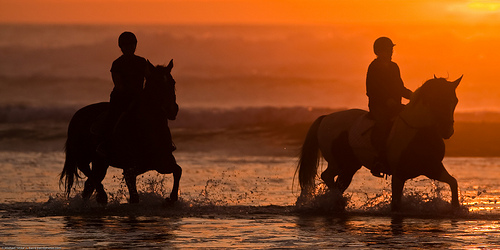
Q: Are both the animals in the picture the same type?
A: Yes, all the animals are horses.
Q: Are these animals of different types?
A: No, all the animals are horses.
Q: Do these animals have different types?
A: No, all the animals are horses.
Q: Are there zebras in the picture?
A: No, there are no zebras.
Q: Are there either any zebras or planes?
A: No, there are no zebras or planes.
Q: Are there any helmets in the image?
A: Yes, there is a helmet.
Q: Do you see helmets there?
A: Yes, there is a helmet.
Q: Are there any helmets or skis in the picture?
A: Yes, there is a helmet.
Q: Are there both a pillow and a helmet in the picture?
A: No, there is a helmet but no pillows.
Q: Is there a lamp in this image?
A: No, there are no lamps.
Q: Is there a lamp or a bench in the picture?
A: No, there are no lamps or benches.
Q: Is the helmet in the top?
A: Yes, the helmet is in the top of the image.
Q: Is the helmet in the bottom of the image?
A: No, the helmet is in the top of the image.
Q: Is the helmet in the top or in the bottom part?
A: The helmet is in the top of the image.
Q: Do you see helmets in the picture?
A: Yes, there is a helmet.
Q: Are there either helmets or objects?
A: Yes, there is a helmet.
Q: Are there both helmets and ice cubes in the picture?
A: No, there is a helmet but no ice cubes.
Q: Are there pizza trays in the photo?
A: No, there are no pizza trays.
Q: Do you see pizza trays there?
A: No, there are no pizza trays.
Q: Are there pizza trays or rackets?
A: No, there are no pizza trays or rackets.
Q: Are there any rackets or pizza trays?
A: No, there are no pizza trays or rackets.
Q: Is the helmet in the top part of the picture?
A: Yes, the helmet is in the top of the image.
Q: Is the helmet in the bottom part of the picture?
A: No, the helmet is in the top of the image.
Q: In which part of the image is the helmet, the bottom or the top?
A: The helmet is in the top of the image.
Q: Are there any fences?
A: No, there are no fences.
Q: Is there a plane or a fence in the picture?
A: No, there are no fences or airplanes.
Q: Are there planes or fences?
A: No, there are no fences or planes.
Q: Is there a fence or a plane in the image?
A: No, there are no fences or airplanes.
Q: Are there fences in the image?
A: No, there are no fences.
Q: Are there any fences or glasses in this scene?
A: No, there are no fences or glasses.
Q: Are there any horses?
A: Yes, there is a horse.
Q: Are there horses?
A: Yes, there is a horse.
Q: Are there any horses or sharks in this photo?
A: Yes, there is a horse.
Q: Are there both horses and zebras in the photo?
A: No, there is a horse but no zebras.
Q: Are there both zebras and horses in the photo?
A: No, there is a horse but no zebras.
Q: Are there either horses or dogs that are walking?
A: Yes, the horse is walking.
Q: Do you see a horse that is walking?
A: Yes, there is a horse that is walking.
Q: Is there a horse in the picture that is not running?
A: Yes, there is a horse that is walking.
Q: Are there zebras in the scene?
A: No, there are no zebras.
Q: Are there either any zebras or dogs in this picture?
A: No, there are no zebras or dogs.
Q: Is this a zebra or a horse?
A: This is a horse.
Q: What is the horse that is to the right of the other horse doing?
A: The horse is walking.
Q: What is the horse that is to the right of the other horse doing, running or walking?
A: The horse is walking.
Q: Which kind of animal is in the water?
A: The animal is a horse.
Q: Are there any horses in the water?
A: Yes, there is a horse in the water.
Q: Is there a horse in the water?
A: Yes, there is a horse in the water.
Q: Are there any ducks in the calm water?
A: No, there is a horse in the water.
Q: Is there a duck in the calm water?
A: No, there is a horse in the water.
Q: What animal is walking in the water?
A: The horse is walking in the water.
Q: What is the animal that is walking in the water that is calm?
A: The animal is a horse.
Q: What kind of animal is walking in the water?
A: The animal is a horse.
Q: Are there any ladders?
A: No, there are no ladders.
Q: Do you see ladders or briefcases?
A: No, there are no ladders or briefcases.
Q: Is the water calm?
A: Yes, the water is calm.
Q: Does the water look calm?
A: Yes, the water is calm.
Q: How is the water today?
A: The water is calm.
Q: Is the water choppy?
A: No, the water is calm.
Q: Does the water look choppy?
A: No, the water is calm.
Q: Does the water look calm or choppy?
A: The water is calm.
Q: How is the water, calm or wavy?
A: The water is calm.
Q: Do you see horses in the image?
A: Yes, there is a horse.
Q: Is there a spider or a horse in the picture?
A: Yes, there is a horse.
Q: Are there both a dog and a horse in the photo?
A: No, there is a horse but no dogs.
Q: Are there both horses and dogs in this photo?
A: No, there is a horse but no dogs.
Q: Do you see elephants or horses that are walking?
A: Yes, the horse is walking.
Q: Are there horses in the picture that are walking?
A: Yes, there is a horse that is walking.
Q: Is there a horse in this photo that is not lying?
A: Yes, there is a horse that is walking.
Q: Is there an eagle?
A: No, there are no eagles.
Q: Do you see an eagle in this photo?
A: No, there are no eagles.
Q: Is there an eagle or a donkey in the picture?
A: No, there are no eagles or donkeys.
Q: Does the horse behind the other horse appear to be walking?
A: Yes, the horse is walking.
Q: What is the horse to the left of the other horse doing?
A: The horse is walking.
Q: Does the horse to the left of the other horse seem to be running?
A: No, the horse is walking.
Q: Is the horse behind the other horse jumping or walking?
A: The horse is walking.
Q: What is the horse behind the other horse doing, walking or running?
A: The horse is walking.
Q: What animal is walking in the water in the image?
A: The horse is walking in the water.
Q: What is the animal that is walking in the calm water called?
A: The animal is a horse.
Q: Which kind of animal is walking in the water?
A: The animal is a horse.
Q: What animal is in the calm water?
A: The horse is in the water.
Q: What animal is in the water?
A: The horse is in the water.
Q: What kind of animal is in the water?
A: The animal is a horse.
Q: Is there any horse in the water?
A: Yes, there is a horse in the water.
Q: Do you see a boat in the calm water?
A: No, there is a horse in the water.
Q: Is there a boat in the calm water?
A: No, there is a horse in the water.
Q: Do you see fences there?
A: No, there are no fences.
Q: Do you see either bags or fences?
A: No, there are no fences or bags.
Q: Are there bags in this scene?
A: No, there are no bags.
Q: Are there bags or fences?
A: No, there are no bags or fences.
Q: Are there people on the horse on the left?
A: Yes, there is a person on the horse.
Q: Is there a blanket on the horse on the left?
A: No, there is a person on the horse.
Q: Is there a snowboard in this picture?
A: No, there are no snowboards.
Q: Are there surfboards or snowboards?
A: No, there are no snowboards or surfboards.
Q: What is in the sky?
A: The sun is in the sky.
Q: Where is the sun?
A: The sun is in the sky.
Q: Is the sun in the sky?
A: Yes, the sun is in the sky.